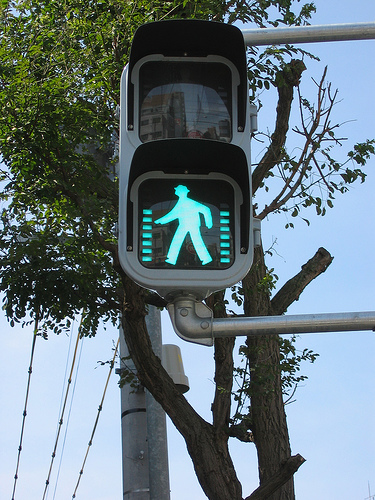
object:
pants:
[188, 228, 213, 265]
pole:
[163, 289, 375, 346]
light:
[118, 18, 254, 286]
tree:
[0, 0, 375, 500]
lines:
[71, 336, 120, 500]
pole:
[119, 303, 170, 500]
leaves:
[11, 320, 14, 327]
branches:
[251, 58, 307, 198]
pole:
[241, 23, 374, 50]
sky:
[0, 0, 375, 500]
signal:
[130, 171, 243, 280]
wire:
[45, 311, 84, 500]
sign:
[139, 184, 234, 269]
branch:
[270, 246, 334, 315]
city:
[140, 83, 231, 143]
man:
[154, 184, 214, 265]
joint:
[164, 289, 214, 346]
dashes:
[142, 256, 153, 262]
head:
[174, 184, 190, 198]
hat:
[174, 185, 191, 193]